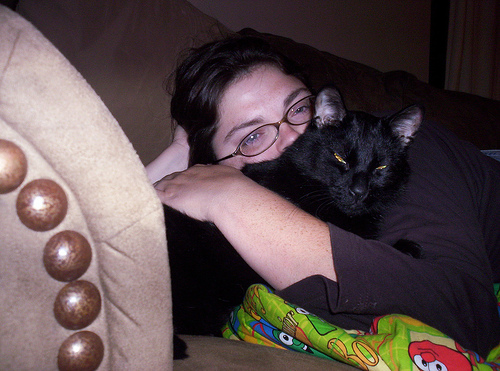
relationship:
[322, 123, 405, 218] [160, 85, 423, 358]
face of cat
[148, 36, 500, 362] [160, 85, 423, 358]
woman holding cat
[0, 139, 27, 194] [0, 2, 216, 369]
rivet in couch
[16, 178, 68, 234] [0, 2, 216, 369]
rivet in couch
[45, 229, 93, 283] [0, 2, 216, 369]
rivet in couch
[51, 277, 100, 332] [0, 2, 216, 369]
rivet in couch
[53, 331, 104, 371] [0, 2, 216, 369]
rivet in couch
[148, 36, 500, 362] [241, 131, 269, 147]
woman has right-eye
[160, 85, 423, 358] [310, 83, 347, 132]
cat has right-ear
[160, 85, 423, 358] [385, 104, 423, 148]
cat has a left-ear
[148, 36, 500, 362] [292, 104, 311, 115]
woman has left-eye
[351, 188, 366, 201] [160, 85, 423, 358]
nose of cat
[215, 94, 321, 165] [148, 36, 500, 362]
glasses on woman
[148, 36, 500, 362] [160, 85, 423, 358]
woman holding onto cat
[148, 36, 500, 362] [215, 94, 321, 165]
woman wearing their glasses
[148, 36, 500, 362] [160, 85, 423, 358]
woman laying with cat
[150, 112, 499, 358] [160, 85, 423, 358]
arm around cat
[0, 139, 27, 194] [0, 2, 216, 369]
rivet on couch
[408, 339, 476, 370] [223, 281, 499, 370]
character on blanket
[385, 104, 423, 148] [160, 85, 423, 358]
left-ear on cat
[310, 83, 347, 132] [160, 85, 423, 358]
right-ear on cat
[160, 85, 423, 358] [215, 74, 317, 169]
cat beside face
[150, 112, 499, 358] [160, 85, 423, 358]
arm on cat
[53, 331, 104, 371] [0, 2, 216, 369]
rivet on couch